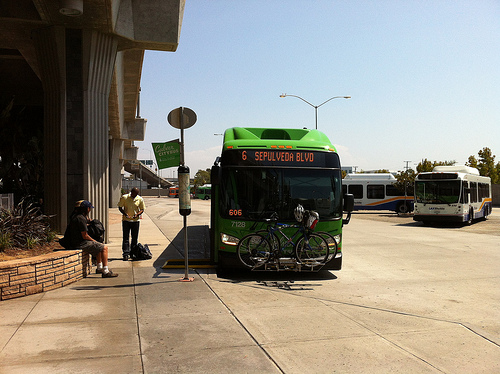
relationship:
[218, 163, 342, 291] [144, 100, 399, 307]
bikes on bus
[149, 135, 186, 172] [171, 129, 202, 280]
sign on pole